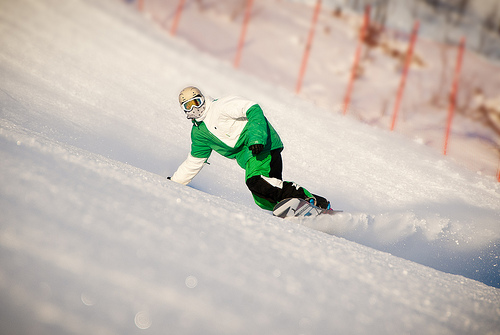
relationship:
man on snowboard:
[166, 85, 330, 218] [271, 195, 334, 225]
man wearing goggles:
[166, 85, 330, 218] [182, 93, 204, 110]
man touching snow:
[166, 85, 330, 218] [0, 1, 497, 332]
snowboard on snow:
[272, 197, 344, 219] [0, 1, 497, 332]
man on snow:
[166, 85, 330, 218] [83, 140, 441, 330]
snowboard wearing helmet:
[272, 197, 344, 219] [179, 84, 211, 122]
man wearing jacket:
[166, 85, 330, 218] [166, 92, 286, 187]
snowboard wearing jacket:
[272, 197, 344, 219] [171, 98, 283, 185]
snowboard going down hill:
[272, 197, 344, 219] [45, 155, 322, 321]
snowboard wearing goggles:
[272, 197, 344, 219] [180, 95, 203, 110]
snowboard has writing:
[229, 181, 360, 240] [281, 202, 320, 218]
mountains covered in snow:
[24, 12, 458, 291] [126, 202, 303, 291]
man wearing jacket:
[166, 85, 330, 218] [147, 109, 277, 169]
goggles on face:
[177, 98, 207, 111] [179, 86, 206, 126]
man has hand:
[166, 85, 330, 218] [249, 142, 279, 162]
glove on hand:
[230, 141, 275, 166] [249, 142, 279, 162]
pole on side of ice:
[230, 0, 260, 82] [110, 61, 465, 176]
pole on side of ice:
[292, 0, 321, 95] [110, 61, 465, 176]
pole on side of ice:
[341, 0, 378, 112] [110, 61, 465, 176]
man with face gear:
[162, 81, 432, 321] [164, 74, 204, 118]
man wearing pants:
[166, 85, 330, 218] [241, 170, 346, 237]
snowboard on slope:
[272, 197, 344, 219] [8, 7, 495, 334]